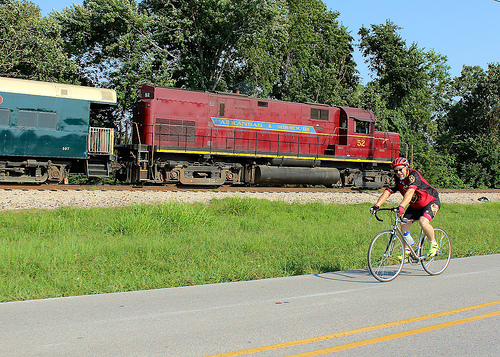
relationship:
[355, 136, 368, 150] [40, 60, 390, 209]
number on train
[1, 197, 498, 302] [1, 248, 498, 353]
grass between road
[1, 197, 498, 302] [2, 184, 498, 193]
grass between tracks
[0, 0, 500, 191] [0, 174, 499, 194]
tree lining tracks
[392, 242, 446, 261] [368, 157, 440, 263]
shoes on cyclist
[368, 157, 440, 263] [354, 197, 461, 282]
cyclist riding bicycle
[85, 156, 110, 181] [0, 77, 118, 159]
stairs leading to car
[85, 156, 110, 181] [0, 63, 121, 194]
stairs leading to train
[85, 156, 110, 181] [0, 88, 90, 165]
stairs leading to compartment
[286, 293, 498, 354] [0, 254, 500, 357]
line on road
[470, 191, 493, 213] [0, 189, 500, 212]
debris on rocks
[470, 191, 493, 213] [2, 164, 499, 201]
debris on train track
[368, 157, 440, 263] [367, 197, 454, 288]
cyclist riding bike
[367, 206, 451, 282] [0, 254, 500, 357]
bike on road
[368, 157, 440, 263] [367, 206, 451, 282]
cyclist riding bike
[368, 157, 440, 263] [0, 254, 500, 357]
cyclist on road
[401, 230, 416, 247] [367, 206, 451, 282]
bottle attached to bike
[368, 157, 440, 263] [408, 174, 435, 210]
cyclist wearing shirt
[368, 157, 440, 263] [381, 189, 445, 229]
cyclist wearing shorts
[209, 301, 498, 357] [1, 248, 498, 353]
line painted on road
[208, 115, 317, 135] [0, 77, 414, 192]
banner on train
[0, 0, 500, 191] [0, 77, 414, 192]
tree next to train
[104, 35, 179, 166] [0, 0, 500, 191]
tree next to tree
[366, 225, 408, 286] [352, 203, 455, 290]
wheel on bike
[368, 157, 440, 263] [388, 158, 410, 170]
cyclist wearing helmet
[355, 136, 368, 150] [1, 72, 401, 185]
number on train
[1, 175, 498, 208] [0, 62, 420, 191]
rocks next to train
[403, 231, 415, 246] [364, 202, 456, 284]
bottle attached to bike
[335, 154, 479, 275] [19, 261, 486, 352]
cyclist on road